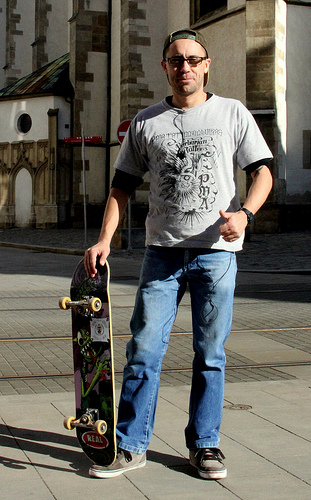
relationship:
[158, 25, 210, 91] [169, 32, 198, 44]
cap has adjustable band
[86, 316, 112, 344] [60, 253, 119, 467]
white sticker on skateboard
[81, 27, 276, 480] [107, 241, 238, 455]
man wearing jeans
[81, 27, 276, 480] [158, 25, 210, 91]
man wearing cap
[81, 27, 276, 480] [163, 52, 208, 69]
man wearing glasses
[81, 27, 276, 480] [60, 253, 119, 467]
man holding skateboard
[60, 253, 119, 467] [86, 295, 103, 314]
skateboard has wheel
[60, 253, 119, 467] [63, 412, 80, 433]
skateboard has wheel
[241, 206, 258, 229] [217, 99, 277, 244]
watch on arm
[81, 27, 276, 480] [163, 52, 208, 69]
man has glasses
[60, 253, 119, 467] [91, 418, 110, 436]
skateboard has wheel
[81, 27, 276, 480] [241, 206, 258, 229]
man has watch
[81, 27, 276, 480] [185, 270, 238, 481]
man has leg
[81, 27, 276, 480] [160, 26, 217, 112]
man has head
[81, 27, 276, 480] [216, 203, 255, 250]
man has hand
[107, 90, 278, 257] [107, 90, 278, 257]
shirt under shirt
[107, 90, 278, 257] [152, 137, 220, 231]
shirt has design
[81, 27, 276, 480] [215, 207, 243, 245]
man holding thumb up